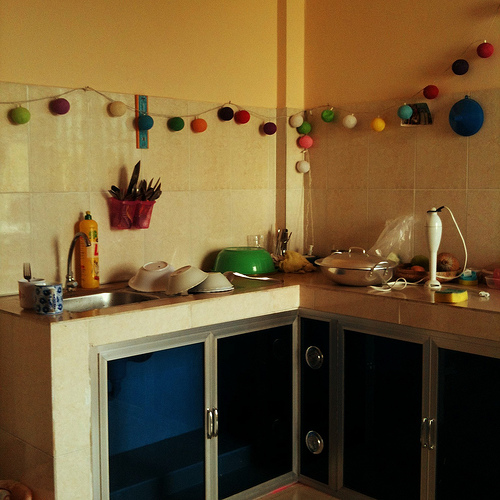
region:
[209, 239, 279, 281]
upside down green bowl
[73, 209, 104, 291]
tall yellow bottle on the counter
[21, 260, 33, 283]
fork in a cup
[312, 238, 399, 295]
silver pan with a lid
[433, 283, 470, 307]
yellow and green sponge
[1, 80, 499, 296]
earth toned backsplash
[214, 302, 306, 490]
the cupboard is blue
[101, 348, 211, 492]
the cupboard is blue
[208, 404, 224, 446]
the handles are silver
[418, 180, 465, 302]
the mixer is white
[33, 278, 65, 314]
the bowl is blue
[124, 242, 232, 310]
a pile of white bowls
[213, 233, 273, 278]
a green bowl on the counter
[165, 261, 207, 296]
an upside down white bowl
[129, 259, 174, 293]
an upside down white bowl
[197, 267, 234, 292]
an upside down white bowl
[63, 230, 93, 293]
a chrome kitchen faucet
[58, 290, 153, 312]
a brushed metal kitchen sink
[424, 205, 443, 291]
a white immersion blender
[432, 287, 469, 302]
a two sided sponge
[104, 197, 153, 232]
a wall mounted red basket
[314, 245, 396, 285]
a chrome wok pan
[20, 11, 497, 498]
this is a kitchen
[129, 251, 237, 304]
white bowls flipped over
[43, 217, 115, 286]
a curved kitchen faucet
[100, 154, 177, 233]
a set of silverware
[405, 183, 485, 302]
this is a hand mixer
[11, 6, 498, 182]
multicolored garland hanging up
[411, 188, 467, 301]
the hand mixer is white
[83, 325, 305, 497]
blue lower kitchen cabinets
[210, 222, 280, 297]
a green flipped bowl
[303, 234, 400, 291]
a silver pot and lid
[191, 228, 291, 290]
green item on counter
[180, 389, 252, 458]
handles on the cabinets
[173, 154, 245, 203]
wall in the room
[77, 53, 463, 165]
items above the counter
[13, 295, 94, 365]
corner of the counter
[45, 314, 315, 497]
blue cabinets under counter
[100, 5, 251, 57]
yellow wall above items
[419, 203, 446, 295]
A white handheld mixer.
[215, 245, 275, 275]
A large green bowl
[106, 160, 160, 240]
Eating utensils in a basket on the wall.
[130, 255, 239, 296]
Bowls upside down.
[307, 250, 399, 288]
A silver pot.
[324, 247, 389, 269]
A clear lid with a silver handle.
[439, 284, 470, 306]
A yellow and green sponge.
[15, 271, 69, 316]
Coffee mugs by the sink.